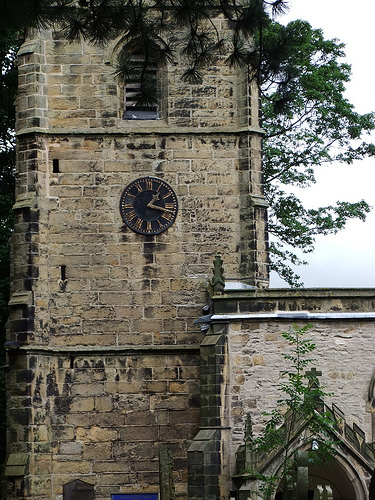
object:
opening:
[52, 158, 58, 174]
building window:
[111, 25, 175, 129]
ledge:
[23, 346, 200, 350]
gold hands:
[146, 204, 174, 217]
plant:
[240, 323, 335, 498]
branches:
[257, 37, 284, 62]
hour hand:
[145, 193, 161, 207]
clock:
[118, 178, 178, 237]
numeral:
[145, 179, 154, 190]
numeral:
[136, 182, 143, 192]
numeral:
[125, 190, 136, 199]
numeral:
[125, 211, 138, 222]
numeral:
[147, 222, 152, 229]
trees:
[256, 6, 373, 288]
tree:
[129, 0, 298, 84]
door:
[269, 406, 357, 498]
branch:
[272, 238, 310, 287]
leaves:
[224, 30, 246, 70]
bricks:
[187, 182, 215, 196]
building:
[203, 282, 370, 408]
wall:
[223, 315, 373, 475]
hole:
[61, 267, 65, 281]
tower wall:
[9, 41, 267, 382]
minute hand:
[169, 210, 175, 215]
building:
[3, 11, 269, 499]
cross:
[304, 366, 322, 394]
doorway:
[260, 407, 367, 498]